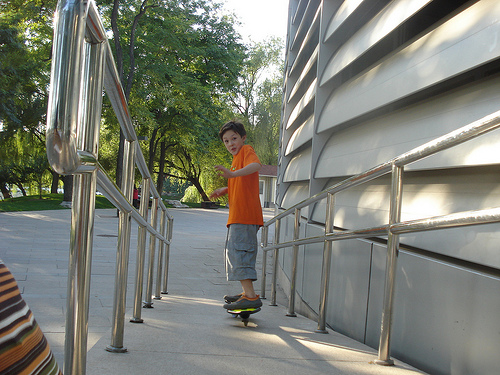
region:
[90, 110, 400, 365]
proud boy skateboarding down ramp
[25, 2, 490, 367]
silver railings on either side of cement ramp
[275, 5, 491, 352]
gray building with large angled slats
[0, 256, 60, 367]
striped brown fabric of sleeve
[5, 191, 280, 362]
patio covered in gray cement tiles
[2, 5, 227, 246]
green trees at edge of patio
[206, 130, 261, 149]
the view of a white wall and chairs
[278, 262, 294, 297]
the view of a white wall and chairs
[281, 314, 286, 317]
the view of a white wall and chairs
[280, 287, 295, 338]
the view of a white wall and chairs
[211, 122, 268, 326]
A young boy standing on a board.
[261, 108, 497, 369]
A metal hand rail.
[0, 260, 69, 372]
A sleeve on a shirt.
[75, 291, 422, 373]
A paved sidewalk.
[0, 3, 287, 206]
A park filled with trees.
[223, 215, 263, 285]
A pair of boy shorts.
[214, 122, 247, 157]
A kid with dark hair.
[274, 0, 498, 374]
A building with lots of vents.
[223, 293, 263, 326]
A skateboard on a walkway.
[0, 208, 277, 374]
A paved area near a building.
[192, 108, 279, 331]
Boy is on a skateboard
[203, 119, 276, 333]
Boy is riding a skateboard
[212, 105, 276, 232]
Boy has a shirt on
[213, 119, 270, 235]
Boy has a orange shirt on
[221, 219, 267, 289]
Boy has shorts on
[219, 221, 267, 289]
Boy has cargo shorts on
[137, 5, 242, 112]
Large trees in the background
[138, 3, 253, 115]
Large green trees in the background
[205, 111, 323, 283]
The boy is next to the railing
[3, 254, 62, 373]
Sleeve of a person